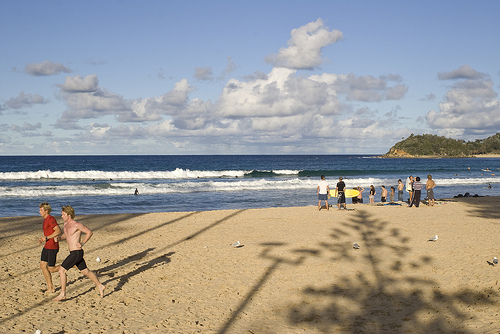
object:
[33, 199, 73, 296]
man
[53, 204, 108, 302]
man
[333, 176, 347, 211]
man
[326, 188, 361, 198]
surfboard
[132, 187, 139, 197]
man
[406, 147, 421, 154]
trees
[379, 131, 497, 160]
mountain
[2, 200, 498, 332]
beach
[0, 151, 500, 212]
water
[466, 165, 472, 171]
person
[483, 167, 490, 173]
person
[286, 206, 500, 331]
trees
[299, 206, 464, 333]
shadow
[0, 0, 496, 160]
sky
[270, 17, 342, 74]
clouds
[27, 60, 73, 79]
cloud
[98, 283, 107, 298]
foot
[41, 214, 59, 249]
shirt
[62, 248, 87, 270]
shorts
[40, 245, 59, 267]
shorts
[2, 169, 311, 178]
waves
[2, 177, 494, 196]
waves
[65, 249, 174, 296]
shadow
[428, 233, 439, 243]
seagull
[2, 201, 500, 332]
sand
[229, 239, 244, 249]
seagull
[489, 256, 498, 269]
seagull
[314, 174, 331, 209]
person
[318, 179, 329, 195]
shirt